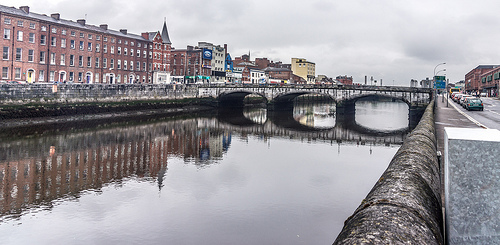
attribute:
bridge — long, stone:
[211, 84, 428, 108]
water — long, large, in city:
[290, 163, 311, 181]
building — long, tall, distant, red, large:
[4, 9, 211, 77]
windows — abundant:
[77, 33, 123, 80]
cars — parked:
[468, 95, 479, 110]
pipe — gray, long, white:
[413, 135, 449, 174]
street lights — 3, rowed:
[431, 56, 449, 101]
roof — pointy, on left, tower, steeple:
[152, 17, 180, 40]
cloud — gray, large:
[351, 23, 420, 44]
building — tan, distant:
[291, 54, 319, 86]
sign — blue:
[203, 48, 211, 59]